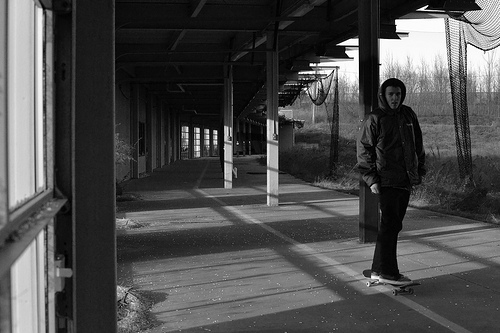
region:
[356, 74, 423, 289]
a young man on a skateboard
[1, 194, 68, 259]
the window sill is dirty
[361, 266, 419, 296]
a skateboard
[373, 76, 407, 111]
the man has a hood on his head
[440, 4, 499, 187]
net is hanging up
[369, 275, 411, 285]
white soles on the shoes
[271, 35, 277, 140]
electrical outlet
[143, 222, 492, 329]
sunlight shining on the ground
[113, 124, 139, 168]
the bush has no leaves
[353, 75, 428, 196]
the man has a long sleeve jacket on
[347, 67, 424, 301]
a man riding on a skateboard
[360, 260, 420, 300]
a skateboard rolling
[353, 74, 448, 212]
a man with a black jacket on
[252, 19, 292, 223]
a metal support beam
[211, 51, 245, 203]
a metal support beam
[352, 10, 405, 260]
a metal support beam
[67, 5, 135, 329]
a metal support beam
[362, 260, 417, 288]
vans brand shoes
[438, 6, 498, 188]
a handing chain net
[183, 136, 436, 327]
a white line painted on the concrete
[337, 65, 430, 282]
guy on a skateboard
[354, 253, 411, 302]
skateboard on the ground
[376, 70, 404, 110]
guy with his hood up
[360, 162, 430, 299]
guy is wearing pants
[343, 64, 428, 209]
guy is wearing a jacket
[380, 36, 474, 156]
trees behind the person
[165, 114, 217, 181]
windows to the building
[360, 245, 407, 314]
guy is wearing tennis shoes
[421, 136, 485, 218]
weeds behind the guy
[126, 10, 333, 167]
roof of the building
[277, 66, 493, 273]
a man that is skatebaording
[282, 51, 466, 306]
a man that is skateboarding outside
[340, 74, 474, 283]
a man on a skateboard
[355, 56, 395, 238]
a man riding a skateboard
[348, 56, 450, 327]
a man on a skateboard outside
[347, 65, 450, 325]
a man riding a skateboard outside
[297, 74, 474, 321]
a man on a skateboard on the sidewalk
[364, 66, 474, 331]
a man wearin ga jacket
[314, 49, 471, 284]
a man wearing a hood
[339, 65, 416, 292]
a man wearing pants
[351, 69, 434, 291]
man in black on white skateboard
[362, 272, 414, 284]
man wearing black sneakers with white soles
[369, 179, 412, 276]
man wearing black pants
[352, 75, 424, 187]
man wearing black hooded jacket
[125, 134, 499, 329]
long gray concrete platform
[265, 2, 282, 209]
whte wooden post supporting platform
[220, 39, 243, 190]
white wooden post supporting platform roof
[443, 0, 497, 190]
net hanging from side of building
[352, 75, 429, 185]
man wearing jacket buttoned up with hood over head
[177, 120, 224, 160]
lineof windows lining platform